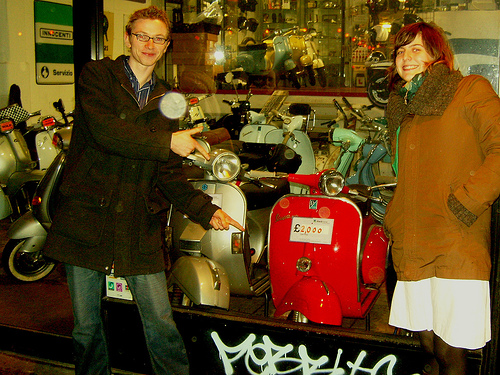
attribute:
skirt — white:
[386, 267, 486, 347]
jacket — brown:
[377, 67, 497, 297]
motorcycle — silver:
[165, 151, 266, 304]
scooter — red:
[265, 157, 393, 327]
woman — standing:
[369, 16, 489, 374]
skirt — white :
[391, 261, 498, 364]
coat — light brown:
[381, 64, 498, 281]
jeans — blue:
[60, 264, 192, 371]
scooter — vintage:
[171, 125, 318, 310]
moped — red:
[250, 167, 397, 329]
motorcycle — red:
[267, 168, 393, 337]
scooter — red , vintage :
[252, 139, 385, 351]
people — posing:
[374, 11, 499, 373]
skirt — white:
[408, 275, 473, 342]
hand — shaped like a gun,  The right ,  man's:
[139, 115, 252, 220]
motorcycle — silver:
[161, 106, 327, 321]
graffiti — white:
[214, 330, 399, 374]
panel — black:
[167, 305, 423, 368]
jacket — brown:
[36, 53, 196, 276]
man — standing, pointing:
[37, 7, 241, 356]